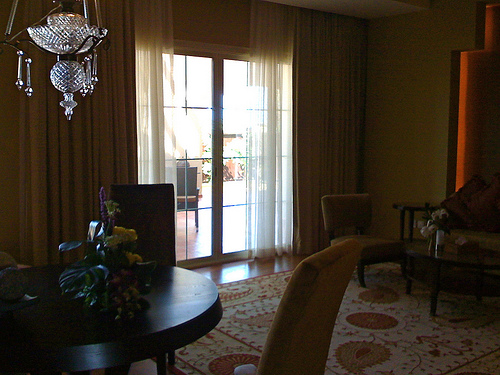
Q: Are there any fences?
A: No, there are no fences.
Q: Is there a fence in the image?
A: No, there are no fences.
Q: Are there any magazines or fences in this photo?
A: No, there are no fences or magazines.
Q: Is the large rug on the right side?
A: Yes, the rug is on the right of the image.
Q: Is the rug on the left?
A: No, the rug is on the right of the image.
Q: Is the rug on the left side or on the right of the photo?
A: The rug is on the right of the image.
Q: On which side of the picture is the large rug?
A: The rug is on the right of the image.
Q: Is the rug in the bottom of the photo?
A: Yes, the rug is in the bottom of the image.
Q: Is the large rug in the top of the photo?
A: No, the rug is in the bottom of the image.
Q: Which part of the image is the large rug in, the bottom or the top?
A: The rug is in the bottom of the image.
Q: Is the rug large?
A: Yes, the rug is large.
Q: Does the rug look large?
A: Yes, the rug is large.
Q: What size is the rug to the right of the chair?
A: The rug is large.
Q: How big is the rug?
A: The rug is large.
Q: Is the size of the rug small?
A: No, the rug is large.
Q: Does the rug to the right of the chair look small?
A: No, the rug is large.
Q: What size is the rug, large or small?
A: The rug is large.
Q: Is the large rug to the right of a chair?
A: Yes, the rug is to the right of a chair.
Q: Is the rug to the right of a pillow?
A: No, the rug is to the right of a chair.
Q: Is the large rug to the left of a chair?
A: No, the rug is to the right of a chair.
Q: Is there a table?
A: Yes, there is a table.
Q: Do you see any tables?
A: Yes, there is a table.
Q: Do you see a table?
A: Yes, there is a table.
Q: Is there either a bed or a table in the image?
A: Yes, there is a table.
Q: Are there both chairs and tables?
A: Yes, there are both a table and a chair.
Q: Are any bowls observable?
A: No, there are no bowls.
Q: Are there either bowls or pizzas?
A: No, there are no bowls or pizzas.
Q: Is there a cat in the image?
A: No, there are no cats.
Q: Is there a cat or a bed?
A: No, there are no cats or beds.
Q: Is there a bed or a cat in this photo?
A: No, there are no cats or beds.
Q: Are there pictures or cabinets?
A: No, there are no pictures or cabinets.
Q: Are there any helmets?
A: No, there are no helmets.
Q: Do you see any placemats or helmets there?
A: No, there are no helmets or placemats.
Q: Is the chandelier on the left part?
A: Yes, the chandelier is on the left of the image.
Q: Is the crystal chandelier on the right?
A: No, the chandelier is on the left of the image.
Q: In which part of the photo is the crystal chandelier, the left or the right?
A: The chandelier is on the left of the image.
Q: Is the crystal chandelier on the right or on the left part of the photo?
A: The chandelier is on the left of the image.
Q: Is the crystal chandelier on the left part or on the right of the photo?
A: The chandelier is on the left of the image.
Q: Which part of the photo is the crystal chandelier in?
A: The chandelier is on the left of the image.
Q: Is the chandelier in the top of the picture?
A: Yes, the chandelier is in the top of the image.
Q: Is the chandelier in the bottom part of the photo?
A: No, the chandelier is in the top of the image.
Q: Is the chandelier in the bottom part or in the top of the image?
A: The chandelier is in the top of the image.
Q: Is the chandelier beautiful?
A: Yes, the chandelier is beautiful.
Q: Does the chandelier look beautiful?
A: Yes, the chandelier is beautiful.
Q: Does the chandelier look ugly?
A: No, the chandelier is beautiful.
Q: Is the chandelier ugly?
A: No, the chandelier is beautiful.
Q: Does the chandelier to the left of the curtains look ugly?
A: No, the chandelier is beautiful.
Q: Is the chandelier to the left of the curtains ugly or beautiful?
A: The chandelier is beautiful.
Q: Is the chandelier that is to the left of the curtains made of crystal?
A: Yes, the chandelier is made of crystal.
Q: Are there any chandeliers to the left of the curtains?
A: Yes, there is a chandelier to the left of the curtains.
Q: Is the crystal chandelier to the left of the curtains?
A: Yes, the chandelier is to the left of the curtains.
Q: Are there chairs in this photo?
A: Yes, there is a chair.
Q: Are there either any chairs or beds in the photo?
A: Yes, there is a chair.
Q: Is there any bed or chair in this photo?
A: Yes, there is a chair.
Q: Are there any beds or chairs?
A: Yes, there is a chair.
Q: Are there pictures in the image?
A: No, there are no pictures.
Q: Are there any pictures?
A: No, there are no pictures.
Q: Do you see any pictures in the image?
A: No, there are no pictures.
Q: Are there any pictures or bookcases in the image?
A: No, there are no pictures or bookcases.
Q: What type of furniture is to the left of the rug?
A: The piece of furniture is a chair.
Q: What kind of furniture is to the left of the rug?
A: The piece of furniture is a chair.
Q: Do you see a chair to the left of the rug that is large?
A: Yes, there is a chair to the left of the rug.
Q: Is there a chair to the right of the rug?
A: No, the chair is to the left of the rug.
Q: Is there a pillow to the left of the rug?
A: No, there is a chair to the left of the rug.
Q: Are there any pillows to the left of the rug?
A: No, there is a chair to the left of the rug.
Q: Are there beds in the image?
A: No, there are no beds.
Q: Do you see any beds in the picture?
A: No, there are no beds.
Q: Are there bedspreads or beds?
A: No, there are no beds or bedspreads.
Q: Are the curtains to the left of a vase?
A: No, the curtains are to the left of the chair.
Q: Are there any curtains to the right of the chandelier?
A: Yes, there are curtains to the right of the chandelier.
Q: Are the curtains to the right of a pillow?
A: No, the curtains are to the right of the chandelier.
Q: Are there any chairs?
A: Yes, there is a chair.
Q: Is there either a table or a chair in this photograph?
A: Yes, there is a chair.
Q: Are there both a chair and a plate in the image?
A: No, there is a chair but no plates.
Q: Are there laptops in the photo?
A: No, there are no laptops.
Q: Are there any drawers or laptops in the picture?
A: No, there are no laptops or drawers.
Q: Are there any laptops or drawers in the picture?
A: No, there are no laptops or drawers.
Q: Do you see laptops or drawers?
A: No, there are no laptops or drawers.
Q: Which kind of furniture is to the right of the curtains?
A: The piece of furniture is a chair.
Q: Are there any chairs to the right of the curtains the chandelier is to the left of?
A: Yes, there is a chair to the right of the curtains.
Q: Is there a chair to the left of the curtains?
A: No, the chair is to the right of the curtains.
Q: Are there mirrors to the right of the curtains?
A: No, there is a chair to the right of the curtains.